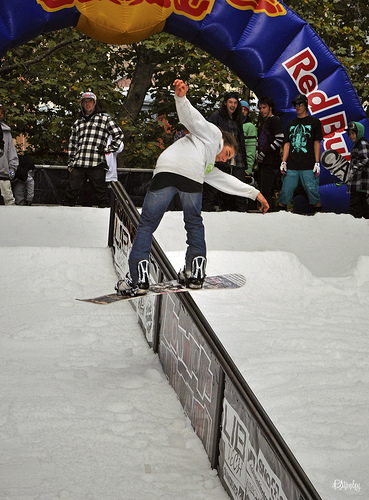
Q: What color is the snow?
A: White.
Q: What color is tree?
A: Green.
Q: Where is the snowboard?
A: The rail.